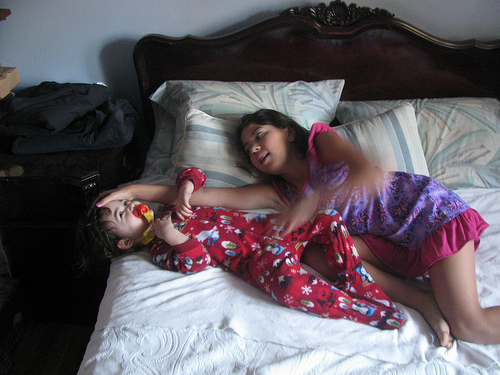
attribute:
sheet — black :
[3, 79, 139, 153]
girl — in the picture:
[88, 107, 498, 354]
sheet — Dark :
[10, 77, 133, 154]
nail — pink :
[90, 196, 105, 208]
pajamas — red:
[146, 167, 407, 330]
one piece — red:
[148, 166, 405, 330]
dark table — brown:
[0, 147, 127, 272]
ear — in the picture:
[118, 231, 140, 253]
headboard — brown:
[127, 0, 499, 112]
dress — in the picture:
[245, 111, 486, 294]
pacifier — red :
[133, 195, 164, 221]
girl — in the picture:
[216, 105, 497, 344]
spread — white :
[72, 183, 497, 373]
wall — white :
[0, 0, 499, 85]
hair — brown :
[87, 194, 144, 269]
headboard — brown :
[92, 6, 498, 79]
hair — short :
[93, 214, 111, 250]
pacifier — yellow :
[131, 201, 151, 224]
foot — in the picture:
[359, 281, 407, 333]